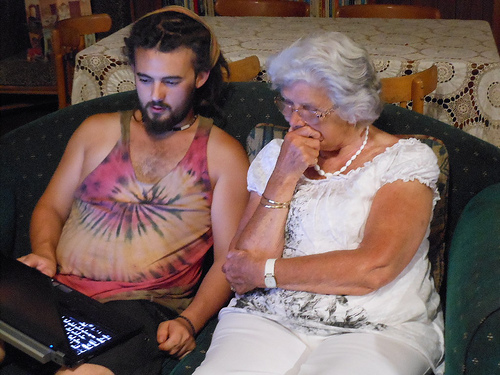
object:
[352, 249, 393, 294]
elbow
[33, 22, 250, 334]
man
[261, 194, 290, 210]
bracelets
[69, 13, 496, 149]
tablecloth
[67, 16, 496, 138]
table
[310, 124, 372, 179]
neclace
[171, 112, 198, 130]
necklace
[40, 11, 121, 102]
chair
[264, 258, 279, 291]
watch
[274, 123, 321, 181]
hand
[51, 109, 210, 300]
shirt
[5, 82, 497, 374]
couch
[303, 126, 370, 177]
beaded necklace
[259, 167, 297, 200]
wrist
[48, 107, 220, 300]
tank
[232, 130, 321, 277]
arm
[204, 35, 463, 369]
woman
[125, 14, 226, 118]
hair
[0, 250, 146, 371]
laptop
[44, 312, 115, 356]
keyboard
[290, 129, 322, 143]
mouth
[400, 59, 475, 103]
design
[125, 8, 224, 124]
dredd locks